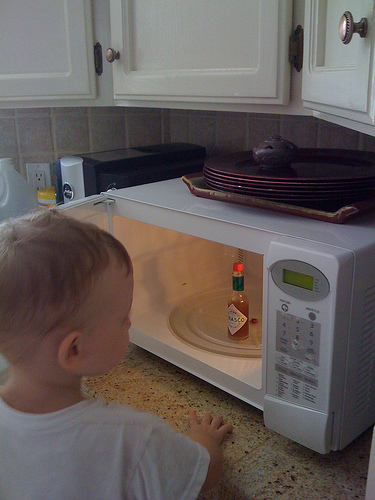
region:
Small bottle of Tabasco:
[225, 260, 251, 340]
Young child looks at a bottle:
[1, 204, 235, 499]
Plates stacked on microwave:
[200, 140, 374, 208]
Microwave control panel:
[263, 256, 331, 405]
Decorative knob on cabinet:
[336, 9, 369, 44]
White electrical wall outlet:
[22, 161, 52, 189]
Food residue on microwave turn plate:
[248, 316, 258, 324]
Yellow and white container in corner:
[35, 184, 57, 210]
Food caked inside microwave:
[181, 280, 188, 286]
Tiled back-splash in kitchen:
[0, 107, 372, 191]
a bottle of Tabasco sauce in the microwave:
[218, 257, 254, 349]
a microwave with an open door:
[44, 192, 307, 411]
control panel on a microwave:
[266, 294, 324, 402]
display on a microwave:
[279, 270, 315, 289]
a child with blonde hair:
[3, 216, 141, 370]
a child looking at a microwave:
[2, 219, 345, 426]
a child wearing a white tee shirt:
[0, 307, 208, 499]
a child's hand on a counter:
[173, 397, 243, 446]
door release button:
[256, 385, 342, 461]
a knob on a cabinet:
[336, 13, 366, 44]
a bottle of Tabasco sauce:
[225, 258, 253, 340]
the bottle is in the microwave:
[222, 255, 255, 345]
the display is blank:
[281, 268, 315, 294]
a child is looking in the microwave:
[1, 207, 261, 498]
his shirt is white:
[2, 388, 205, 495]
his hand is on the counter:
[169, 393, 239, 493]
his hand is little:
[182, 406, 236, 455]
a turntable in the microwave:
[168, 280, 274, 359]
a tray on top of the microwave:
[171, 164, 372, 227]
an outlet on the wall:
[23, 158, 54, 198]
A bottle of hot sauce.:
[223, 261, 250, 341]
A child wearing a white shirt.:
[0, 206, 234, 499]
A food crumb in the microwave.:
[250, 313, 259, 325]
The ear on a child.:
[55, 328, 89, 375]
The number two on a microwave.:
[291, 315, 302, 324]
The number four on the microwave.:
[277, 318, 288, 329]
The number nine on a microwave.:
[305, 338, 316, 346]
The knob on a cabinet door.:
[336, 9, 366, 46]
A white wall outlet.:
[23, 160, 51, 190]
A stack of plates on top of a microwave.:
[200, 148, 374, 206]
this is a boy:
[20, 233, 200, 498]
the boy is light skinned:
[70, 347, 98, 386]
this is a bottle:
[227, 266, 245, 347]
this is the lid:
[232, 259, 244, 270]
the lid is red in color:
[230, 259, 245, 267]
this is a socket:
[30, 162, 51, 189]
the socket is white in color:
[28, 162, 45, 175]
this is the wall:
[39, 117, 81, 140]